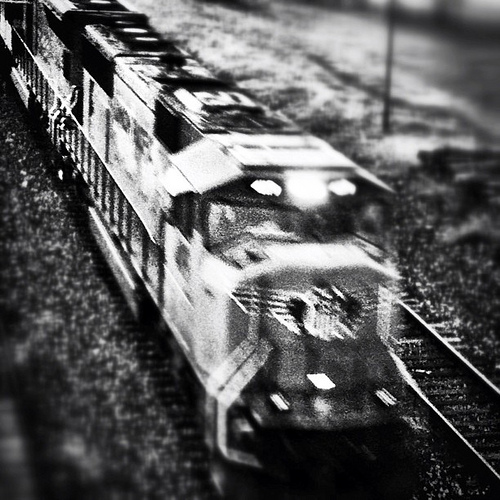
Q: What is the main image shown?
A: A train.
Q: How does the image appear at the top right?
A: Blurry.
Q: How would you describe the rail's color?
A: Black.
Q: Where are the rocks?
A: Under and next to the tracks.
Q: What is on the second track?
A: The second track is empty.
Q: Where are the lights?
A: Above the locomotive windshield.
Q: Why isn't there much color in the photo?
A: Photo is black and white.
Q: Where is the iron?
A: Below the train.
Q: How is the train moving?
A: Forward.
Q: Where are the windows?
A: Side of the train.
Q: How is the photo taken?
A: Black and white.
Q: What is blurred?
A: The picture.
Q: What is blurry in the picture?
A: Train.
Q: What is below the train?
A: Tracks.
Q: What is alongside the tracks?
A: Rocks.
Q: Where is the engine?
A: Front of the train.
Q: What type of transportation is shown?
A: Train.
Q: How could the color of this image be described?
A: Black and white.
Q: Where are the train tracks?
A: Ground under train.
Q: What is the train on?
A: Tracks.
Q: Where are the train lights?
A: Front of train.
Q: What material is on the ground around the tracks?
A: Gravel.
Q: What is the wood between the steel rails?
A: Railroad ties.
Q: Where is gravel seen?
A: On ground.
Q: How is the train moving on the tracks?
A: An engineer driver.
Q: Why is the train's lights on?
A: To make the train visible.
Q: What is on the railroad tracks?
A: Train.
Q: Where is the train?
A: Railroad tracks.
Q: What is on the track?
A: A train.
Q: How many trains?
A: 1.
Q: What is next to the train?
A: A pole.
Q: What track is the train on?
A: The left track.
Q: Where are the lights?
A: On top of the train.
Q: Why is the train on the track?
A: Traveling.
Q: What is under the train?
A: Gravel.